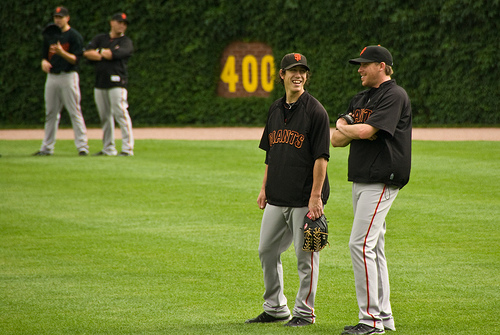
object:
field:
[1, 121, 500, 334]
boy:
[253, 49, 331, 325]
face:
[282, 68, 310, 92]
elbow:
[357, 128, 369, 142]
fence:
[1, 1, 500, 127]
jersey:
[40, 23, 84, 72]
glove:
[303, 212, 329, 250]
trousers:
[41, 72, 91, 151]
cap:
[348, 45, 395, 66]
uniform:
[254, 94, 331, 322]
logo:
[291, 52, 304, 63]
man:
[83, 9, 136, 157]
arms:
[100, 42, 134, 60]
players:
[329, 41, 410, 334]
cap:
[109, 11, 133, 25]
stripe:
[70, 73, 85, 130]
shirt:
[86, 30, 134, 87]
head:
[106, 12, 132, 34]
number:
[219, 53, 239, 94]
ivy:
[1, 1, 500, 128]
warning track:
[1, 127, 500, 140]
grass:
[1, 139, 499, 334]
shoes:
[245, 310, 288, 324]